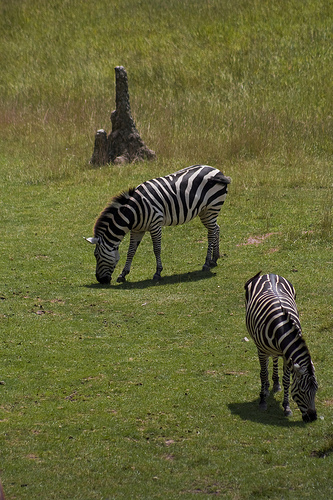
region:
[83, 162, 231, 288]
a zebra eating in a field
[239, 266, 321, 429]
zebra grazing in some grass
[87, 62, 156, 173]
a tree stump in a plane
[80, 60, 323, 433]
animals in a savannah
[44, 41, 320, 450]
a grassy african land scape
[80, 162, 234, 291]
a small zebra with big black stripes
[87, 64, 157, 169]
a weird structure in the grass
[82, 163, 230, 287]
a zebra eating some grass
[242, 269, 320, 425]
a zebra having a snack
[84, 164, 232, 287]
a black and white zebra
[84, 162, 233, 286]
a striped zebra eating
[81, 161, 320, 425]
a pair of eating zebras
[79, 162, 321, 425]
two zebras in the grass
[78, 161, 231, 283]
a zebra leaning over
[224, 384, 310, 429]
a zebra shadow in grass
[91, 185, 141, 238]
a zebras striped mohawk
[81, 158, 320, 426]
two zebras grazing in grass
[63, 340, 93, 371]
patch of green grass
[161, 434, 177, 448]
patch of dirt in grass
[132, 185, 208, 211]
black stripes on zebra fur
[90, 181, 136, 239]
black and white zebra mane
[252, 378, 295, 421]
black zebra hooves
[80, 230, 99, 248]
one zebra ear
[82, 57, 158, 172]
rock structure in grass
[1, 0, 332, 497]
green grass field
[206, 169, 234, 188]
black zebra tail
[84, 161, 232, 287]
a zebra in a field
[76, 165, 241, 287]
black and white large striped mammal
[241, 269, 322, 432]
zebra grazing in a field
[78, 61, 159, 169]
tree stump extends in the air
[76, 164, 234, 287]
zebra feeding on grass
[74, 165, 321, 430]
two zebras in a savannah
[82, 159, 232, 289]
a zebra standing in a prarie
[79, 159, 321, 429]
two animals biting on plants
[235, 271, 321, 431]
zebra walking around in plain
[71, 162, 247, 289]
an animal standing in place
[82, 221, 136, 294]
the zebra is eating grass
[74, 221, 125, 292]
the zebra is eating grass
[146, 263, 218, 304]
the shadow of a zebra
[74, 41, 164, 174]
a large rock in back